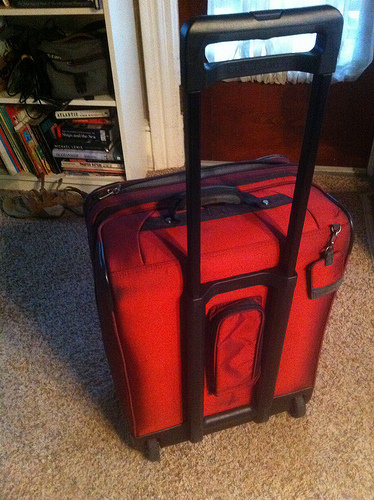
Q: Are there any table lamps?
A: No, there are no table lamps.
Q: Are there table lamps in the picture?
A: No, there are no table lamps.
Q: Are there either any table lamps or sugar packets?
A: No, there are no table lamps or sugar packets.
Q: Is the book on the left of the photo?
A: Yes, the book is on the left of the image.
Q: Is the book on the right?
A: No, the book is on the left of the image.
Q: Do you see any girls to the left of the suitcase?
A: No, there is a book to the left of the suitcase.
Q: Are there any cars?
A: No, there are no cars.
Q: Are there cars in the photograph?
A: No, there are no cars.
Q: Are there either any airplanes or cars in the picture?
A: No, there are no cars or airplanes.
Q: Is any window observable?
A: Yes, there is a window.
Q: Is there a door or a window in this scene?
A: Yes, there is a window.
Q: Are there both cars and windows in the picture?
A: No, there is a window but no cars.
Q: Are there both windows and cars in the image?
A: No, there is a window but no cars.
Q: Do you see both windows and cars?
A: No, there is a window but no cars.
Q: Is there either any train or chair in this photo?
A: No, there are no chairs or trains.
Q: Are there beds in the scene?
A: No, there are no beds.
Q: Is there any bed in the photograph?
A: No, there are no beds.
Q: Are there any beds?
A: No, there are no beds.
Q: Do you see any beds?
A: No, there are no beds.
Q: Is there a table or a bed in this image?
A: No, there are no beds or tables.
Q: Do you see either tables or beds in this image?
A: No, there are no beds or tables.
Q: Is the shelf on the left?
A: Yes, the shelf is on the left of the image.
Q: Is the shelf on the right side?
A: No, the shelf is on the left of the image.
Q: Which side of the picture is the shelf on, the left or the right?
A: The shelf is on the left of the image.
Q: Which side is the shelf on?
A: The shelf is on the left of the image.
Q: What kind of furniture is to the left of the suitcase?
A: The piece of furniture is a shelf.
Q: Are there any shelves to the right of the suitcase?
A: No, the shelf is to the left of the suitcase.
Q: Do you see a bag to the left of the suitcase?
A: No, there is a shelf to the left of the suitcase.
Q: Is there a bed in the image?
A: No, there are no beds.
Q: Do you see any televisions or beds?
A: No, there are no beds or televisions.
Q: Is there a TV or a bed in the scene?
A: No, there are no beds or televisions.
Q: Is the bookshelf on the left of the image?
A: Yes, the bookshelf is on the left of the image.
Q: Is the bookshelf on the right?
A: No, the bookshelf is on the left of the image.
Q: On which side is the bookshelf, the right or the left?
A: The bookshelf is on the left of the image.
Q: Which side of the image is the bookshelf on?
A: The bookshelf is on the left of the image.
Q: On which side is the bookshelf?
A: The bookshelf is on the left of the image.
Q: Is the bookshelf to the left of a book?
A: Yes, the bookshelf is to the left of a book.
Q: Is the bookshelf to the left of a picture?
A: No, the bookshelf is to the left of a book.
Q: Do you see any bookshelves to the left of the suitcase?
A: Yes, there is a bookshelf to the left of the suitcase.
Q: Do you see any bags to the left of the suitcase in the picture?
A: No, there is a bookshelf to the left of the suitcase.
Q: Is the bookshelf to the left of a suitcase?
A: Yes, the bookshelf is to the left of a suitcase.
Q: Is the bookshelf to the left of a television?
A: No, the bookshelf is to the left of a suitcase.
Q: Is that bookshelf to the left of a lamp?
A: No, the bookshelf is to the left of a book.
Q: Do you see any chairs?
A: No, there are no chairs.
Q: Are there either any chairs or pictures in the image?
A: No, there are no chairs or pictures.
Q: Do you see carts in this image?
A: No, there are no carts.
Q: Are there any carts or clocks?
A: No, there are no carts or clocks.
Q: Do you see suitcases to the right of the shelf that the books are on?
A: Yes, there is a suitcase to the right of the shelf.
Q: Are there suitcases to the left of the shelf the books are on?
A: No, the suitcase is to the right of the shelf.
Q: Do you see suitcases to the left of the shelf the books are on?
A: No, the suitcase is to the right of the shelf.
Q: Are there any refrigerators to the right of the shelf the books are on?
A: No, there is a suitcase to the right of the shelf.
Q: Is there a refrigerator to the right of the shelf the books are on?
A: No, there is a suitcase to the right of the shelf.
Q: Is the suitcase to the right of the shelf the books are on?
A: Yes, the suitcase is to the right of the shelf.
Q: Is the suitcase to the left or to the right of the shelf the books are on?
A: The suitcase is to the right of the shelf.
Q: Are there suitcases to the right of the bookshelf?
A: Yes, there is a suitcase to the right of the bookshelf.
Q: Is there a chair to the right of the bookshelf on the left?
A: No, there is a suitcase to the right of the bookshelf.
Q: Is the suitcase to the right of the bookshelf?
A: Yes, the suitcase is to the right of the bookshelf.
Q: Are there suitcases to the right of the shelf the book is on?
A: Yes, there is a suitcase to the right of the shelf.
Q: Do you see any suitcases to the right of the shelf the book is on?
A: Yes, there is a suitcase to the right of the shelf.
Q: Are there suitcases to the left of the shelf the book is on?
A: No, the suitcase is to the right of the shelf.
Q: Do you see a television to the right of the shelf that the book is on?
A: No, there is a suitcase to the right of the shelf.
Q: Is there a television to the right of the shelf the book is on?
A: No, there is a suitcase to the right of the shelf.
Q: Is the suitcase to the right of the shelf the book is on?
A: Yes, the suitcase is to the right of the shelf.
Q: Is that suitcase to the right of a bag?
A: No, the suitcase is to the right of the shelf.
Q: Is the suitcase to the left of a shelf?
A: No, the suitcase is to the right of a shelf.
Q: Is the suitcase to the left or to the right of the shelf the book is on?
A: The suitcase is to the right of the shelf.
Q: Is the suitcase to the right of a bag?
A: No, the suitcase is to the right of a book.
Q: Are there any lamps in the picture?
A: No, there are no lamps.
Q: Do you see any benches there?
A: No, there are no benches.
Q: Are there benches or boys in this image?
A: No, there are no benches or boys.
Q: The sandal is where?
A: The sandal is on the floor.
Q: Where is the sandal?
A: The sandal is on the floor.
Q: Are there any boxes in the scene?
A: No, there are no boxes.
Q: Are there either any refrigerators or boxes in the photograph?
A: No, there are no boxes or refrigerators.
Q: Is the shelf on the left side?
A: Yes, the shelf is on the left of the image.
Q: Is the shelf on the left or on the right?
A: The shelf is on the left of the image.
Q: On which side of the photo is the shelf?
A: The shelf is on the left of the image.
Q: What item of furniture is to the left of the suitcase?
A: The piece of furniture is a shelf.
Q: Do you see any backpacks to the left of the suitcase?
A: No, there is a shelf to the left of the suitcase.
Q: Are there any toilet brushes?
A: No, there are no toilet brushes.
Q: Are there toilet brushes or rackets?
A: No, there are no toilet brushes or rackets.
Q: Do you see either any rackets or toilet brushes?
A: No, there are no toilet brushes or rackets.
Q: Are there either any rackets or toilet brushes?
A: No, there are no toilet brushes or rackets.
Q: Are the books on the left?
A: Yes, the books are on the left of the image.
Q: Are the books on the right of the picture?
A: No, the books are on the left of the image.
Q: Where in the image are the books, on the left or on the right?
A: The books are on the left of the image.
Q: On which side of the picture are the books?
A: The books are on the left of the image.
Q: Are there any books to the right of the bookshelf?
A: Yes, there are books to the right of the bookshelf.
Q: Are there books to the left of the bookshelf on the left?
A: No, the books are to the right of the bookshelf.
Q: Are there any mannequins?
A: No, there are no mannequins.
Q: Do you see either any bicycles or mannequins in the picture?
A: No, there are no mannequins or bicycles.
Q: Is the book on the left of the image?
A: Yes, the book is on the left of the image.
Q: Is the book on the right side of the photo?
A: No, the book is on the left of the image.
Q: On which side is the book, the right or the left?
A: The book is on the left of the image.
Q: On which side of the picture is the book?
A: The book is on the left of the image.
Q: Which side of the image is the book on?
A: The book is on the left of the image.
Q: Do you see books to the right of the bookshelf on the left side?
A: Yes, there is a book to the right of the bookshelf.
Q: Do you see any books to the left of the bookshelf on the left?
A: No, the book is to the right of the bookshelf.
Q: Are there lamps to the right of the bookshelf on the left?
A: No, there is a book to the right of the bookshelf.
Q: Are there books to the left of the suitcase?
A: Yes, there is a book to the left of the suitcase.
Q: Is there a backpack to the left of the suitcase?
A: No, there is a book to the left of the suitcase.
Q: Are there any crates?
A: No, there are no crates.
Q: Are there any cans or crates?
A: No, there are no crates or cans.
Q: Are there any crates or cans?
A: No, there are no crates or cans.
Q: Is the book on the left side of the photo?
A: Yes, the book is on the left of the image.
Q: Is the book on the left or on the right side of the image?
A: The book is on the left of the image.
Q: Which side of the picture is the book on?
A: The book is on the left of the image.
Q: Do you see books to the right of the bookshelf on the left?
A: Yes, there is a book to the right of the bookshelf.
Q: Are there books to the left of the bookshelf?
A: No, the book is to the right of the bookshelf.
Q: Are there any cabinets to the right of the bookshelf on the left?
A: No, there is a book to the right of the bookshelf.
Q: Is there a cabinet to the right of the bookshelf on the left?
A: No, there is a book to the right of the bookshelf.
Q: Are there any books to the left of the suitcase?
A: Yes, there is a book to the left of the suitcase.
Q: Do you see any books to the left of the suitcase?
A: Yes, there is a book to the left of the suitcase.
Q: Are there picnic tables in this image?
A: No, there are no picnic tables.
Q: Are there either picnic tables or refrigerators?
A: No, there are no picnic tables or refrigerators.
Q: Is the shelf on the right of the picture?
A: No, the shelf is on the left of the image.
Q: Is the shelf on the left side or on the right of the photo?
A: The shelf is on the left of the image.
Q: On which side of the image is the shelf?
A: The shelf is on the left of the image.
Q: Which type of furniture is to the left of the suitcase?
A: The piece of furniture is a shelf.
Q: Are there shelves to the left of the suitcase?
A: Yes, there is a shelf to the left of the suitcase.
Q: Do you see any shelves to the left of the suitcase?
A: Yes, there is a shelf to the left of the suitcase.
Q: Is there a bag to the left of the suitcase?
A: No, there is a shelf to the left of the suitcase.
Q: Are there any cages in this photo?
A: No, there are no cages.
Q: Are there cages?
A: No, there are no cages.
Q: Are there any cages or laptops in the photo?
A: No, there are no cages or laptops.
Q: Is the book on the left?
A: Yes, the book is on the left of the image.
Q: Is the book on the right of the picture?
A: No, the book is on the left of the image.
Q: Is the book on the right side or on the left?
A: The book is on the left of the image.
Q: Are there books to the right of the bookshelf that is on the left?
A: Yes, there is a book to the right of the bookshelf.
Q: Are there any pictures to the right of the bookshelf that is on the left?
A: No, there is a book to the right of the bookshelf.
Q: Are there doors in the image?
A: Yes, there is a door.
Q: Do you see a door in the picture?
A: Yes, there is a door.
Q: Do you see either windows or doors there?
A: Yes, there is a door.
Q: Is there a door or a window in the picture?
A: Yes, there is a door.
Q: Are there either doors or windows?
A: Yes, there is a door.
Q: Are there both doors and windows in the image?
A: Yes, there are both a door and windows.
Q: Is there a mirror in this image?
A: No, there are no mirrors.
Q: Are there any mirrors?
A: No, there are no mirrors.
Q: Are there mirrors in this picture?
A: No, there are no mirrors.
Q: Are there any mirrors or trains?
A: No, there are no mirrors or trains.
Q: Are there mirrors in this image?
A: No, there are no mirrors.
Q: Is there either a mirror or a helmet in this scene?
A: No, there are no mirrors or helmets.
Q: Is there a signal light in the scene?
A: No, there are no traffic lights.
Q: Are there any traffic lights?
A: No, there are no traffic lights.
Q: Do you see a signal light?
A: No, there are no traffic lights.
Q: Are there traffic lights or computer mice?
A: No, there are no traffic lights or computer mice.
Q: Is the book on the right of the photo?
A: No, the book is on the left of the image.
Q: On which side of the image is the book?
A: The book is on the left of the image.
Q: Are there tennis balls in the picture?
A: No, there are no tennis balls.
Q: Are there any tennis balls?
A: No, there are no tennis balls.